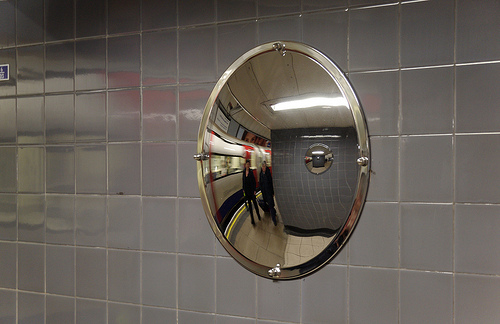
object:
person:
[240, 160, 262, 228]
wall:
[0, 0, 499, 323]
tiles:
[399, 135, 454, 203]